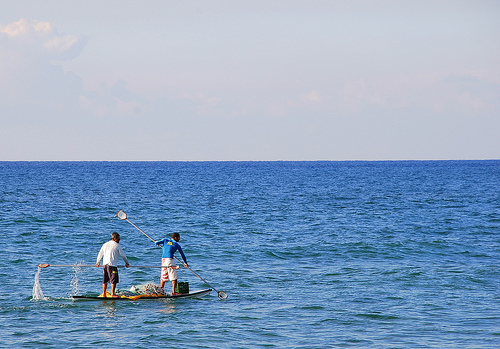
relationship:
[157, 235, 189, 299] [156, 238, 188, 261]
man wears shirt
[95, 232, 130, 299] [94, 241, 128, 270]
man wears shirt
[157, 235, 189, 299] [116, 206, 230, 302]
man has paddle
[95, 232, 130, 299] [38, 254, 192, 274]
man has paddle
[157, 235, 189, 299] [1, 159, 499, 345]
man in ocean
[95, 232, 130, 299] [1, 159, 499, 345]
man in ocean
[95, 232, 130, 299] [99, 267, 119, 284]
man wears shorts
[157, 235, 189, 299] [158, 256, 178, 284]
man has shorts